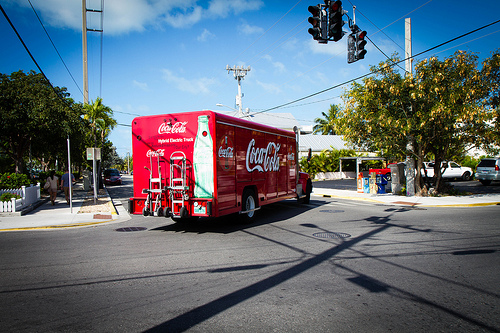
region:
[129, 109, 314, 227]
red Coca Cola truck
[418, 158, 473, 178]
white truck in parking lot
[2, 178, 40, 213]
white picket fence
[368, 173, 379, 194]
yellow newspaper box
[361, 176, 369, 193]
blue paper box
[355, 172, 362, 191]
red paper box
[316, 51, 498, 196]
tree with yellow flowers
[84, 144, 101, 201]
street sign is backwards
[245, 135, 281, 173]
Coca Cola written on truck in white letters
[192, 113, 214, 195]
drawing of empty Coke bottle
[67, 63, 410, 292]
a truck in an intersection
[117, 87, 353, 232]
a coca cola truck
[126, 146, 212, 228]
a pair of metal dollys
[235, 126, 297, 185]
a company brand name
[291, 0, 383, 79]
a few street lights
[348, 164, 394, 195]
a row of newspapers for sale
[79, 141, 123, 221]
a metal street sign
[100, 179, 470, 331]
a street intersection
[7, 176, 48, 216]
a white picket fence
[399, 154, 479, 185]
a white pickup truck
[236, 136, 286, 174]
The coca-cola logo in white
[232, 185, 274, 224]
A truck wheel with guard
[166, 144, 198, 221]
A dolly on back of truck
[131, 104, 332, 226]
A coca-cola delivery truck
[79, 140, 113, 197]
A street sign from behind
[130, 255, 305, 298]
Black paved road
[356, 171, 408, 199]
Multiple garbage cans with lids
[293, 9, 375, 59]
Traffic lights hanging overhead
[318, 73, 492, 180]
A green tree with yellow blooms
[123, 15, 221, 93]
A blue sky with few clouds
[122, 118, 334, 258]
the truck is red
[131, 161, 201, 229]
there are two wheelers on the back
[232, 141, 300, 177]
the cocacola letters are white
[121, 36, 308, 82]
the sky is blue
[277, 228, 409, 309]
there is shadow on the ground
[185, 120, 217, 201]
there is a cocacola bottle drawing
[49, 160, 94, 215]
the two people are walking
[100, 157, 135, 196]
the car is parked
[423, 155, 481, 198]
the car is white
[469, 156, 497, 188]
the truck is silver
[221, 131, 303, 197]
White letters that say coca-cola.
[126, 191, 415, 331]
A shadow on the street.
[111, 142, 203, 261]
Silver dollies for loading and unloading.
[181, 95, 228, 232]
White picture of a bottle.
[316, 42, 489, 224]
Green trees by the road.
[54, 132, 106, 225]
Two signs on side walk.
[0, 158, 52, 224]
White picket fence by side walk.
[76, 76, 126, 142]
Two palm trees.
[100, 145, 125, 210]
Car parked on side of road.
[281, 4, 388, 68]
Three black traffic lights.